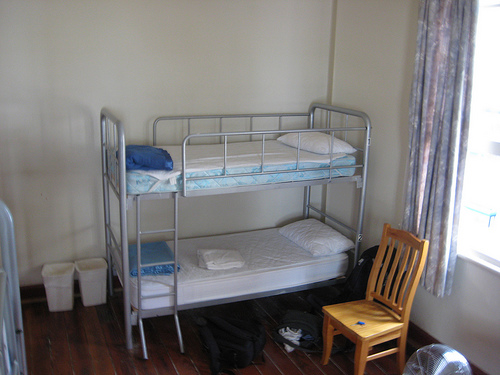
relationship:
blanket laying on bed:
[115, 144, 175, 170] [100, 101, 373, 359]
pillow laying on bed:
[276, 130, 357, 156] [100, 101, 373, 359]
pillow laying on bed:
[277, 217, 355, 257] [100, 101, 373, 359]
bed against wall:
[100, 101, 373, 359] [1, 0, 338, 288]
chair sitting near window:
[320, 221, 430, 374] [455, 0, 500, 261]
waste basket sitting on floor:
[73, 257, 108, 307] [22, 283, 439, 374]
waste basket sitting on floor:
[42, 262, 76, 313] [22, 283, 439, 374]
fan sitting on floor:
[401, 341, 473, 374] [22, 283, 439, 374]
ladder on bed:
[135, 190, 184, 360] [100, 101, 373, 359]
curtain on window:
[399, 2, 479, 299] [455, 0, 500, 261]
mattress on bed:
[111, 226, 349, 309] [100, 101, 373, 359]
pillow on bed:
[276, 130, 357, 156] [100, 101, 373, 359]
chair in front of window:
[320, 221, 430, 374] [455, 0, 500, 261]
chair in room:
[320, 221, 430, 374] [1, 0, 500, 374]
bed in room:
[100, 101, 373, 359] [1, 0, 500, 374]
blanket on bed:
[115, 144, 175, 170] [100, 101, 373, 359]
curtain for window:
[399, 2, 479, 299] [455, 0, 500, 261]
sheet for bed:
[196, 248, 245, 270] [100, 101, 373, 359]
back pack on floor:
[192, 313, 266, 374] [22, 283, 439, 374]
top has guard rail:
[100, 101, 373, 207] [182, 126, 367, 197]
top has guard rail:
[100, 101, 373, 207] [153, 112, 310, 145]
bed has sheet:
[100, 101, 373, 359] [196, 248, 245, 270]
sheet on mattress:
[196, 248, 245, 270] [111, 226, 349, 309]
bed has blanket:
[100, 101, 373, 359] [115, 144, 175, 170]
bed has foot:
[100, 101, 373, 359] [106, 142, 182, 194]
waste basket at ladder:
[73, 257, 108, 307] [135, 190, 184, 360]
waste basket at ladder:
[42, 262, 76, 313] [135, 190, 184, 360]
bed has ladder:
[100, 101, 373, 359] [135, 190, 184, 360]